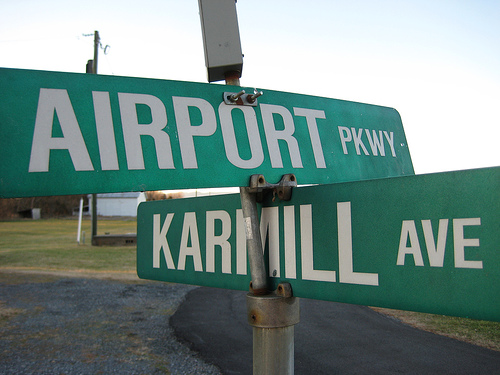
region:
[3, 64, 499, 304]
white and green street signs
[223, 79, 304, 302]
bolts and brackets connecting signs to pole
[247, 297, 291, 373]
pole signs are affixed to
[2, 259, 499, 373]
roads behind the signs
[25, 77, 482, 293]
white lettering on green background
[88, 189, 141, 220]
white building in the background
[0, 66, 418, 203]
green and white street sign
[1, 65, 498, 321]
two green and white street signs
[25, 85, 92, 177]
white letter a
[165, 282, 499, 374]
black concrete road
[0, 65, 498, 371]
two signs on a metal pole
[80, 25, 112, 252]
high wood pole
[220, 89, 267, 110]
two screws with nut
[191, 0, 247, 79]
gray metal box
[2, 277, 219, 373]
gravel with patches of grass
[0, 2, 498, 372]
metal box and two signs on a pole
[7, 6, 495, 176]
muted blue and white sky over signs and pole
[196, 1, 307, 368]
metal gray pole with rectangular box on top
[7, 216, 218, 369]
gravel surface in front of grassy surface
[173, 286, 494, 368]
curved path of black asphalt through grass and gravel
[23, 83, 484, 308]
capital letters for all lettering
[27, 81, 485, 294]
both streets are named streets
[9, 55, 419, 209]
rectangular sign tipping backwards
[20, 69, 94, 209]
white letter on green sign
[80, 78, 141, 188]
white letter on green sign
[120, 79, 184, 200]
white letter on green sign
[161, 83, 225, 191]
white letter on green sign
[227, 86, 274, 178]
white letter on green sign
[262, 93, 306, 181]
white letter on green sign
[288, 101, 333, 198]
white letter on green sign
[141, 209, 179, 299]
white letter on green sign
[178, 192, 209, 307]
white letter on green sign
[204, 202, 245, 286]
white letter on green sign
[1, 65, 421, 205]
green sign on top of pole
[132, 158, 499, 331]
second sign is green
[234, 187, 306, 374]
pole holding signs is silver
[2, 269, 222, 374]
small gravel area beside road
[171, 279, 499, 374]
small roadway between grassy areas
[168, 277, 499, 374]
small roadway is black tar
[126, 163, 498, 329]
second sign reads karmill ave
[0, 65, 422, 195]
top sign reads airport pkwy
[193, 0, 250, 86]
small box above road signs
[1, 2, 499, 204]
sky is mostly clear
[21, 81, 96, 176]
white letter on sign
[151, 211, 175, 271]
white letter on sign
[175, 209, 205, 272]
white letter on sign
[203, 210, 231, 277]
white letter on sign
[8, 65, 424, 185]
green airport sign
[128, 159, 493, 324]
green and white sign that says karmill ave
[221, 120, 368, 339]
street sign on a pole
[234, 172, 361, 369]
street sign on metal pole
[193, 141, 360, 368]
street sign on ametal pole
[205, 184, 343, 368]
pole with street sign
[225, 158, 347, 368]
metal pole with street sign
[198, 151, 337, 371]
metal pole with street sign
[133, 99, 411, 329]
green street sign on metal pole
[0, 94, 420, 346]
A green street sign with white writing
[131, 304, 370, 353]
A paved roadway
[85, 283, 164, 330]
A gravel parking lot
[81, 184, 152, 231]
A white garage with a metal roof